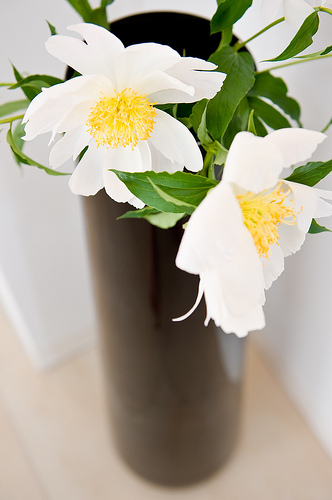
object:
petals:
[222, 115, 329, 193]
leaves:
[204, 20, 257, 152]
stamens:
[120, 118, 128, 149]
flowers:
[170, 115, 332, 343]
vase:
[60, 171, 247, 498]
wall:
[2, 3, 325, 441]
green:
[221, 63, 254, 88]